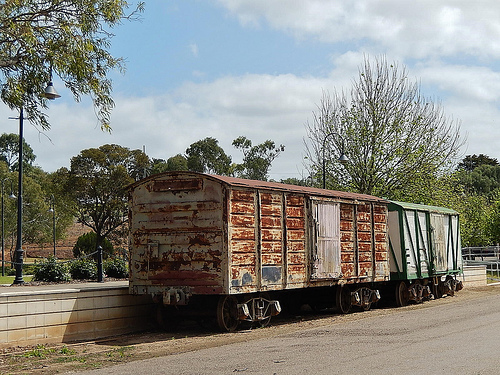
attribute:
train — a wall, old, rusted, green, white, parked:
[114, 178, 466, 334]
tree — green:
[54, 146, 132, 277]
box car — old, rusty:
[120, 177, 388, 334]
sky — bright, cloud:
[259, 27, 327, 77]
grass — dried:
[77, 253, 122, 281]